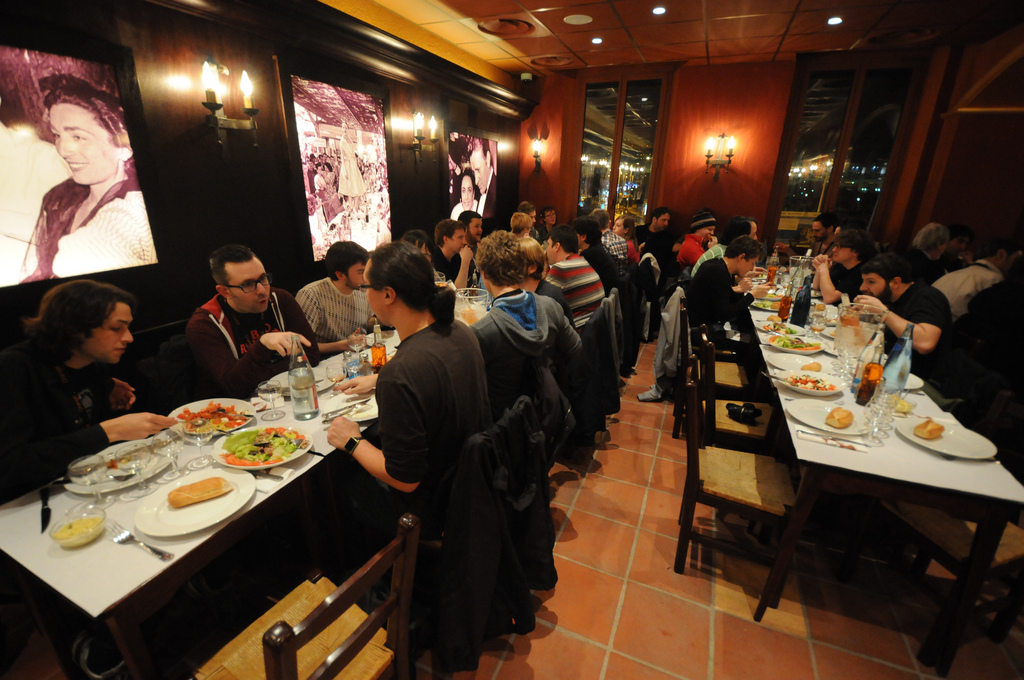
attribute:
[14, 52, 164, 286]
photo — black, white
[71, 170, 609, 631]
table — long, white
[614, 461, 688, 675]
floor — dark orange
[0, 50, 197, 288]
photo — large, black, white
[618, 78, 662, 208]
window — large, reflective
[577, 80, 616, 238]
window — large, reflective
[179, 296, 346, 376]
jacket — black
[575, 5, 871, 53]
recessed lights — white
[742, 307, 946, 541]
table — long, for dining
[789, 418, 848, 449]
cover — for white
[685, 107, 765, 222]
lights — wall, decorative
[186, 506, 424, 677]
chair — wooden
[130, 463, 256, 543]
plate — oblong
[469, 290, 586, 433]
hoodie — blue, gray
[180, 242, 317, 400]
man — seated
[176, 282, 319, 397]
hoodie — red